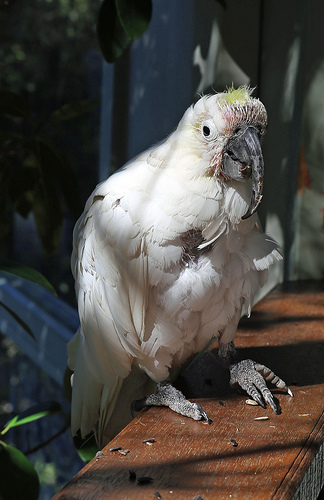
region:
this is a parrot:
[45, 33, 302, 442]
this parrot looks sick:
[58, 44, 302, 433]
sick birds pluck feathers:
[47, 38, 296, 439]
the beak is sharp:
[208, 120, 279, 212]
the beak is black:
[170, 51, 304, 230]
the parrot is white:
[37, 48, 285, 475]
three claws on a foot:
[208, 330, 307, 442]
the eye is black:
[186, 86, 241, 171]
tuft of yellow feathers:
[218, 37, 276, 162]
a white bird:
[69, 89, 297, 437]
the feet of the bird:
[133, 357, 294, 425]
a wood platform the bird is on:
[48, 377, 316, 498]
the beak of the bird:
[222, 130, 265, 216]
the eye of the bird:
[202, 125, 210, 136]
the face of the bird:
[182, 91, 276, 220]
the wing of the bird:
[73, 203, 168, 350]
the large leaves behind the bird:
[92, 3, 154, 64]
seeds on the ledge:
[105, 436, 164, 490]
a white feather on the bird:
[95, 234, 144, 361]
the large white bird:
[65, 80, 293, 450]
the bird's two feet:
[130, 357, 293, 423]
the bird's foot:
[130, 380, 209, 423]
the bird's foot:
[221, 359, 292, 414]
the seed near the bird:
[230, 437, 236, 445]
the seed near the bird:
[218, 398, 224, 406]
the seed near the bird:
[109, 445, 121, 451]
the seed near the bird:
[255, 416, 268, 420]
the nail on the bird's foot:
[255, 395, 266, 407]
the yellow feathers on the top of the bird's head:
[212, 80, 255, 102]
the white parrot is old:
[54, 74, 295, 452]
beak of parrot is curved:
[221, 126, 268, 221]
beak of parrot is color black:
[221, 132, 270, 228]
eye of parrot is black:
[195, 117, 213, 140]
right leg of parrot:
[214, 338, 296, 412]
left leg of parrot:
[131, 377, 206, 435]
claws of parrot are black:
[196, 405, 213, 425]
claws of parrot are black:
[258, 395, 277, 412]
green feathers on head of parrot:
[206, 77, 261, 113]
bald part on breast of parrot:
[168, 225, 217, 278]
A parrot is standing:
[67, 84, 293, 445]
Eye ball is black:
[202, 126, 208, 137]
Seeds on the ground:
[96, 377, 270, 497]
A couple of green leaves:
[0, 399, 49, 498]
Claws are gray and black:
[219, 341, 291, 414]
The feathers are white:
[69, 93, 280, 446]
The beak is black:
[223, 126, 262, 218]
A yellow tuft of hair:
[222, 83, 250, 102]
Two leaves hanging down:
[97, 0, 150, 63]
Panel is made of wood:
[51, 280, 321, 498]